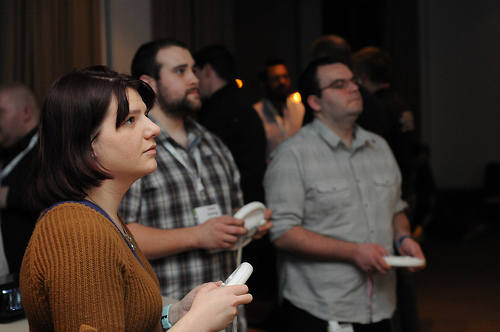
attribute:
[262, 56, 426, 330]
man — middle aged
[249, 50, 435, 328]
man — middle aged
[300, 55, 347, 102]
hair — short, black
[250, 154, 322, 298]
sleeve — rolled up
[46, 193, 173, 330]
sweater — brown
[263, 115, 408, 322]
shirt — button down, open collar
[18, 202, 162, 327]
sweater — brown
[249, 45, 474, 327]
man — dark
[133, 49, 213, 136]
man — middle aged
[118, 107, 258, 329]
shirt — plaid, checkered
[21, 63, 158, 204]
hair — brown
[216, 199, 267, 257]
remote — white, steering wheel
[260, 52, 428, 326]
guy — indoors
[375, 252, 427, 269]
controller — white, wii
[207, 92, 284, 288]
suit — black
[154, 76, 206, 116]
facial hair — dark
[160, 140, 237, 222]
tag — white, ribbon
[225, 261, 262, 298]
controller — white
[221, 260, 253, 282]
remote controller — game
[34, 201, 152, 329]
sweater — ribbed, brown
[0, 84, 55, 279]
man — seated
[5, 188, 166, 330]
sweater — brown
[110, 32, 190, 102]
hair — short, black